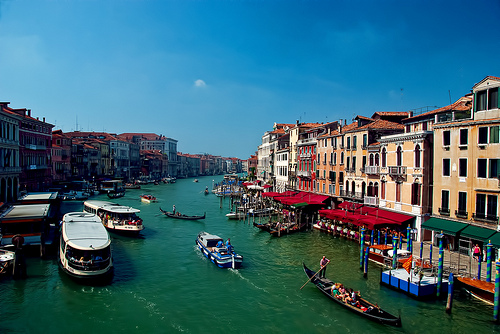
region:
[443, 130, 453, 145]
glass window on building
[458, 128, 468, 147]
glass window on building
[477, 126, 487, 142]
glass window on building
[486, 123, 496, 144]
glass window on building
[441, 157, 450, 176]
glass window on building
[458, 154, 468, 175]
glass window on building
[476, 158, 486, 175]
glass window on building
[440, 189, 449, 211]
glass window on building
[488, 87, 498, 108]
glass window on building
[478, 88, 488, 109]
glass window on building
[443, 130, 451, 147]
glass window on building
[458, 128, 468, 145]
glass window on building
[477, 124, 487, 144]
glass window on building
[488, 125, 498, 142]
glass window on building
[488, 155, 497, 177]
glass window on building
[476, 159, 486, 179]
glass window on building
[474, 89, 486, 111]
glass window on building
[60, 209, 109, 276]
the boat is on the water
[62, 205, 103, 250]
the top is white in color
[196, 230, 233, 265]
the boat is on the water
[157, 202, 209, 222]
a gondola is on the water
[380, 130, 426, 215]
the building is orange in color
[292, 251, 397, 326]
a gondola is carrying people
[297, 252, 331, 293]
the man is holding a paddle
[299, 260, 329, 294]
the paddle is made of wood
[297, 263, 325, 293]
the paddle is brown in color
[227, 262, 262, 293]
the boat is leaving a water trail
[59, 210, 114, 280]
a large boat is on the water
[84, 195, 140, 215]
the boat has a white top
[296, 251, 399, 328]
a gondola is on the water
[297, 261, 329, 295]
the man is holding a paddle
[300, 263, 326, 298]
the paddle is in the water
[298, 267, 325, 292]
the paddle is made of wood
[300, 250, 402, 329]
the gondola is filled with people